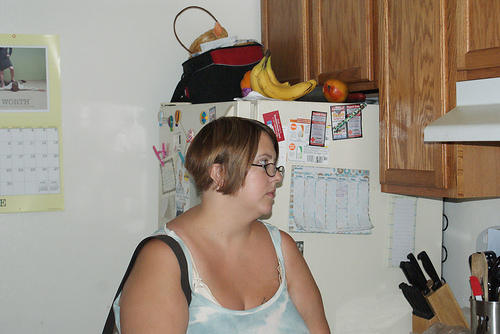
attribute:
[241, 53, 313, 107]
bananas — bunched, sitting, yellow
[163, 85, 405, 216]
fridge — here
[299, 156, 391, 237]
calendar — white, weekly, hanging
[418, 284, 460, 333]
container — wooden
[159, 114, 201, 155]
magnets — stuck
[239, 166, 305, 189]
glasses — lowered, low-profile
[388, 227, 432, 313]
knives — set, seperate, sitting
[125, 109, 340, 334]
lady — wearing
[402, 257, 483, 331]
utensils — bunched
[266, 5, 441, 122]
cabinets — wooden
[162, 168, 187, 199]
papers — attachd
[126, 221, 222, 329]
strap — black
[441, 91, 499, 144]
fan — exhaust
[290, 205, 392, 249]
paper — curled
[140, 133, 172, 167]
clip — attached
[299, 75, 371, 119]
apple — sitting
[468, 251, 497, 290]
spoon — wooden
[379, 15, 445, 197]
door — overhead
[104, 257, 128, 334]
purse — straped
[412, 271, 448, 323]
holder — wooden